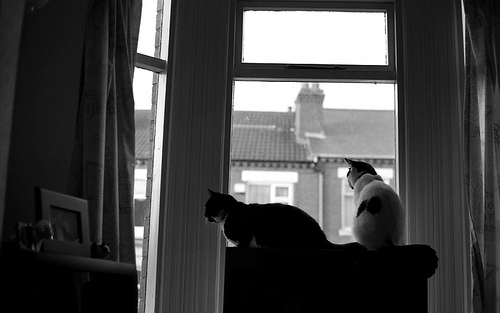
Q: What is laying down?
A: Black cat.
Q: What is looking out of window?
A: Black cat.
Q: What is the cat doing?
A: Sitting on the window.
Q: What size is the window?
A: A large outdoor window.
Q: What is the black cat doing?
A: Looking out of window.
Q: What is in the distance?
A: A tiled roof.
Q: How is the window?
A: Open.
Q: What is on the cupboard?
A: Two cats.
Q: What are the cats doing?
A: Looking outside.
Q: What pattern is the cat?
A: Black and white.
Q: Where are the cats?
A: By the window.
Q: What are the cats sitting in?
A: Window.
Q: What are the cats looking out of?
A: Window.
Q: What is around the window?
A: Curtains.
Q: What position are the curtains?
A: Open.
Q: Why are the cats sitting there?
A: Looking outside.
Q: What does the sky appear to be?
A: Cloudy.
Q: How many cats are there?
A: Two.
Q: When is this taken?
A: During the day.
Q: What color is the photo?
A: Black and white.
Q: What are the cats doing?
A: Sitting.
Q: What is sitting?
A: The cats.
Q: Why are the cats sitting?
A: To rest.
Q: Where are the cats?
A: In the window.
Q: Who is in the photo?
A: There are no people.